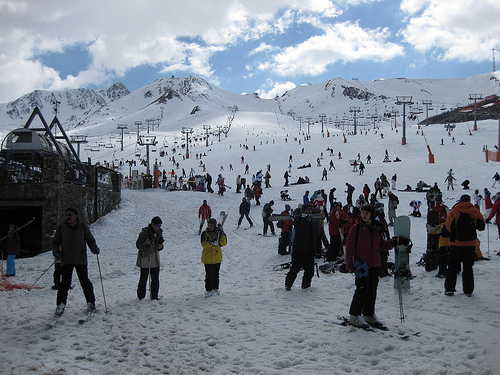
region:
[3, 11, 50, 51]
white clouds in blue sky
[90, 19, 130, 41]
white clouds in blue sky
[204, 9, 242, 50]
white clouds in blue sky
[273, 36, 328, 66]
white clouds in blue sky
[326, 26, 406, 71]
white clouds in blue sky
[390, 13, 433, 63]
white clouds in blue sky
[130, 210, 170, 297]
skier in white snow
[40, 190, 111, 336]
skier in white snow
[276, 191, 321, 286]
skier in white snow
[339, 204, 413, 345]
skier in white snow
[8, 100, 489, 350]
many people on a field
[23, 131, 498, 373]
field is covered with snow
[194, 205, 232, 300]
woman holding skis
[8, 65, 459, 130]
mountains are covered with snow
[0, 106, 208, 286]
a train on left side of field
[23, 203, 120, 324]
person holding snow poles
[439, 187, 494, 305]
a man wears an orange coat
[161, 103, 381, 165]
people skiing on the hill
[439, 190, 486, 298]
man wearing a backpack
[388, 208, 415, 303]
a white snowboard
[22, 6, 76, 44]
white clouds in blue sky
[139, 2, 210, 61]
white clouds in blue sky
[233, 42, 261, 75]
white clouds in blue sky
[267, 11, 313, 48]
white clouds in blue sky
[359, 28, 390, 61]
white clouds in blue sky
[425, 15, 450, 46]
white clouds in blue sky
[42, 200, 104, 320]
skier on snow covered mountain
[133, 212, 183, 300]
skier on snow covered mountain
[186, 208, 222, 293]
skier on snow covered mountain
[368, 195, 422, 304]
person holding snowboard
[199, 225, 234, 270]
person wearing yellow jacket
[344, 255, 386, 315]
person wearing black pants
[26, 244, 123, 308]
person holding ski poles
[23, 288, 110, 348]
person on white skis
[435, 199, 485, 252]
person wearing orange jacket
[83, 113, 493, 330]
multiple peope on top of mountain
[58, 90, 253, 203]
poles line mountain top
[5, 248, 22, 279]
person wearing blue pants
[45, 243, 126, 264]
person wearing dark gloves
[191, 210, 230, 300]
skier on the hill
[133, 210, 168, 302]
skier on the hill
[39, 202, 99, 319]
skier on the hill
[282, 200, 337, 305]
skier on the hill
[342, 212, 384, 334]
skier on the hill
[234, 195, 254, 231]
skier on the hill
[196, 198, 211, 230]
skier on the hill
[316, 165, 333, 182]
skier on the hill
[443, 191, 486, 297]
skier on the hill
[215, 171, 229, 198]
skier on the hill